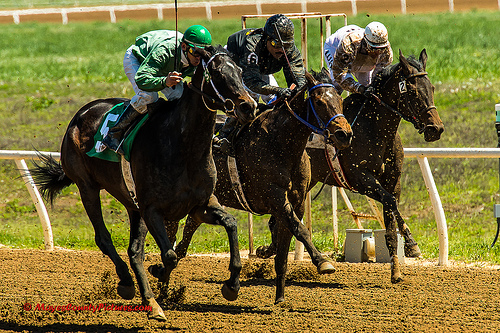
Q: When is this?
A: Daytime.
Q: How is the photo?
A: Clear.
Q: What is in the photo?
A: Horses.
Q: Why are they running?
A: Racing.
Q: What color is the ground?
A: Brown.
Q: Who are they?
A: Racers.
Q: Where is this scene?
A: On a horse race track.